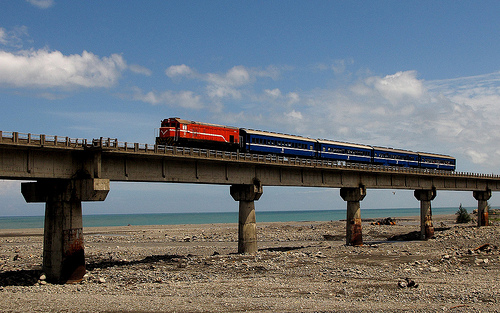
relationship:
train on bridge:
[154, 114, 458, 171] [1, 130, 498, 262]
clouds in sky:
[3, 51, 127, 92] [1, 3, 498, 148]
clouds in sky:
[370, 72, 425, 110] [1, 3, 498, 148]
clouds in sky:
[161, 58, 288, 86] [1, 3, 498, 148]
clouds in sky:
[20, 0, 60, 10] [1, 3, 498, 148]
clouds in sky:
[129, 89, 208, 113] [1, 3, 498, 148]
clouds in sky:
[1, 22, 32, 52] [1, 3, 498, 148]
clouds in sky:
[432, 69, 499, 102] [1, 3, 498, 148]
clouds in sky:
[308, 54, 363, 76] [1, 3, 498, 148]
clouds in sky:
[458, 154, 500, 169] [1, 3, 498, 148]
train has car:
[154, 114, 458, 171] [157, 116, 242, 154]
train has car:
[154, 114, 458, 171] [238, 129, 321, 159]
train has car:
[154, 114, 458, 171] [316, 135, 372, 164]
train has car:
[154, 114, 458, 171] [371, 145, 419, 167]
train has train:
[154, 114, 458, 171] [154, 114, 457, 171]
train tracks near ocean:
[1, 150, 498, 179] [1, 202, 494, 227]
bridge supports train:
[1, 130, 498, 262] [154, 114, 458, 171]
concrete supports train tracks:
[19, 181, 115, 283] [1, 150, 498, 179]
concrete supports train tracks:
[228, 182, 266, 254] [1, 150, 498, 179]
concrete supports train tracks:
[338, 185, 368, 244] [1, 150, 498, 179]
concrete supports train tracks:
[414, 188, 438, 237] [1, 150, 498, 179]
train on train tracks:
[154, 114, 458, 171] [1, 150, 498, 179]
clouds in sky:
[278, 108, 315, 134] [1, 3, 498, 148]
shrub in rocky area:
[452, 203, 473, 225] [6, 207, 496, 309]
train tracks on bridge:
[1, 150, 498, 179] [1, 130, 498, 262]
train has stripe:
[154, 114, 458, 171] [159, 128, 464, 168]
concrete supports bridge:
[474, 190, 492, 228] [1, 130, 498, 262]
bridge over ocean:
[1, 130, 498, 262] [1, 202, 494, 227]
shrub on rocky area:
[452, 203, 473, 225] [6, 207, 496, 309]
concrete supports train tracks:
[474, 190, 492, 228] [1, 150, 498, 179]